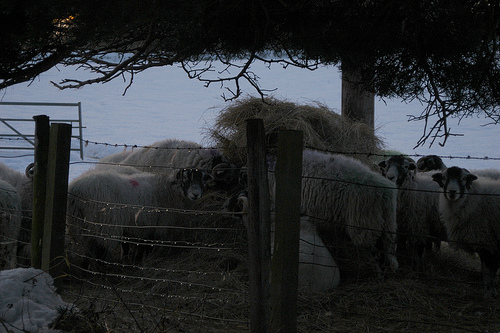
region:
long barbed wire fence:
[68, 185, 223, 297]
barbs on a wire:
[58, 225, 216, 248]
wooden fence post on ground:
[248, 107, 276, 319]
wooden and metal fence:
[3, 111, 304, 273]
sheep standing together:
[48, 127, 232, 264]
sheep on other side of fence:
[82, 140, 234, 260]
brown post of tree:
[332, 58, 389, 125]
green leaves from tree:
[367, 25, 476, 89]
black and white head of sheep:
[381, 150, 418, 175]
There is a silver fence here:
[174, 224, 198, 283]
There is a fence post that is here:
[273, 195, 308, 272]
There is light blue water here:
[143, 93, 158, 114]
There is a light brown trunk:
[341, 91, 373, 129]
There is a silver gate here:
[63, 99, 90, 145]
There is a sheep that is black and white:
[444, 166, 466, 216]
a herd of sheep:
[1, 95, 499, 307]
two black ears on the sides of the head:
[428, 166, 480, 184]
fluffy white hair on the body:
[276, 145, 398, 247]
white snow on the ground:
[2, 45, 497, 217]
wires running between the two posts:
[36, 108, 267, 326]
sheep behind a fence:
[1, 80, 491, 331]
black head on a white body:
[428, 155, 498, 275]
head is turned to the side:
[428, 165, 478, 203]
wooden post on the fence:
[36, 117, 76, 285]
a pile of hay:
[190, 80, 381, 173]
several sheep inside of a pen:
[61, 111, 476, 277]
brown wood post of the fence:
[229, 113, 308, 330]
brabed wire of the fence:
[63, 127, 240, 305]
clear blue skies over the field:
[146, 82, 193, 132]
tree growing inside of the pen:
[16, 1, 486, 90]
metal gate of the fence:
[0, 98, 86, 160]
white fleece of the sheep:
[316, 159, 363, 216]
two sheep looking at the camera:
[380, 147, 495, 257]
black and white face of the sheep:
[173, 164, 216, 209]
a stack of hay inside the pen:
[222, 90, 373, 158]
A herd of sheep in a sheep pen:
[7, 119, 498, 322]